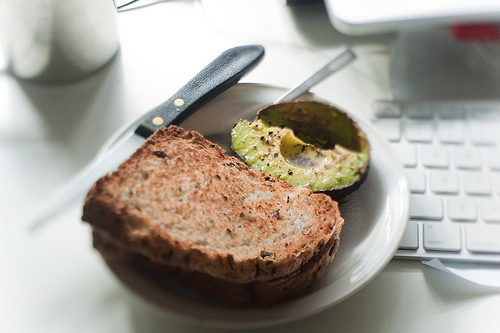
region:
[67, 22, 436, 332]
two pieces of toast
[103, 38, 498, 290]
an avocado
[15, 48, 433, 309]
half of an avocado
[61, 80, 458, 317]
two pieces of wheat bread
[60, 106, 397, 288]
two pieces of toast on a plate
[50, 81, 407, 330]
two pieces of wheat on a plate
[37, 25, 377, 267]
a knife on a plate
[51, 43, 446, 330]
silverware on a plate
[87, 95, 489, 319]
food on a plate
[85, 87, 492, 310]
food on a white plate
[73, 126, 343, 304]
A slice of toasted bread.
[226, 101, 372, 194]
A cut in half avocado.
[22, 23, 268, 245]
A knife on a white plate.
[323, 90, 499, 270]
A computer keyboard.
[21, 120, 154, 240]
A blade on a knife.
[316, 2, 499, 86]
A computer monitor.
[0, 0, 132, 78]
A salt shaker on a table.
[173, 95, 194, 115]
A bolt on a knife.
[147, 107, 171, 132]
A second bolt on a knife.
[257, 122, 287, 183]
spices on a avocado half.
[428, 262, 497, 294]
corner of a white piece of paper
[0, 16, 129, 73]
white mug on the table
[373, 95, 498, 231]
white keyboard and a part of white plate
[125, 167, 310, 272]
a piece of toast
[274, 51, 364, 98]
handle of a silver spoon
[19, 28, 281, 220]
slice of toast and knife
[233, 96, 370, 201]
half eaten half of avocado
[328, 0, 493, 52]
bottom half of computer monitor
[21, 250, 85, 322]
white computer desk with food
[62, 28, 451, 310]
a breakfast plate on a desk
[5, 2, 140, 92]
a white computer mouse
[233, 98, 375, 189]
a half avocado on a plate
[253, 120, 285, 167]
pepper on an avocado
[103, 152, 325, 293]
two toasted slices of bread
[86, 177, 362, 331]
slices of bread on a plate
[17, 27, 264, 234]
a knife propped on a plate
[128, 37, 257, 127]
black handle of a knife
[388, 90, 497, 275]
a white computer keyboard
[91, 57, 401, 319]
avocado and bread on a plate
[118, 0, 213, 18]
wires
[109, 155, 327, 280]
Bread on a plate.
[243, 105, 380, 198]
Avocado on a plate.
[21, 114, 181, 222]
Knife on the plate.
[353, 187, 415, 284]
The plate is white.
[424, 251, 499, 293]
Paper under the keyboard.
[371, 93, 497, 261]
The keyboard is white.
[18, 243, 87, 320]
The desk is white.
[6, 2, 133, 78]
Cup in the background.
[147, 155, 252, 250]
Seasoning on the bread.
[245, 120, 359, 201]
Seasoning on the avocado.